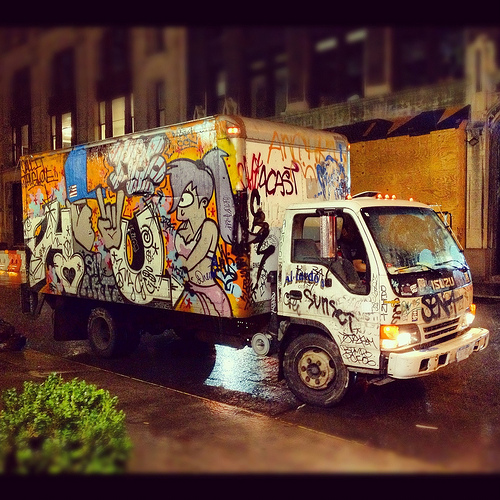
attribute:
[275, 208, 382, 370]
door — passenger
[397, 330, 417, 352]
light — white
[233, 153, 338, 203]
writing — black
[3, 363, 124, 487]
tree — green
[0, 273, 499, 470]
pavement — under, wet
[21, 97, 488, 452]
truck — parked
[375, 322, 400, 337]
light — orange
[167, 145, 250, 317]
character — painted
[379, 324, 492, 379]
bumper — white 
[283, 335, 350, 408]
tire — black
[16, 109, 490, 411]
truck — colorful, white 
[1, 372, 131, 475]
bush — leafy, foreground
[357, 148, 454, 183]
wall — yellow 